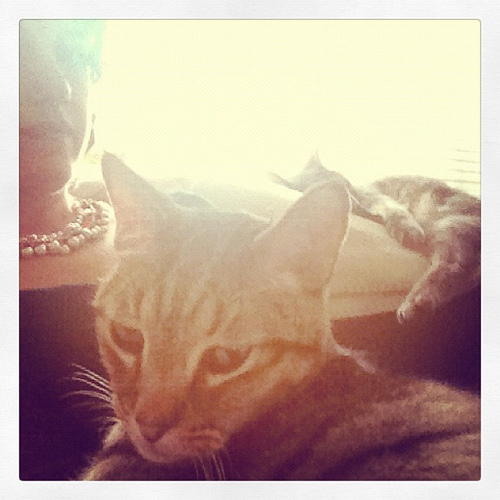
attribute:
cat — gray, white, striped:
[36, 160, 378, 453]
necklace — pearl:
[28, 193, 113, 258]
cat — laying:
[294, 152, 498, 332]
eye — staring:
[213, 339, 258, 385]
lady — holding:
[28, 35, 357, 448]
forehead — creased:
[102, 245, 334, 355]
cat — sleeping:
[292, 131, 493, 338]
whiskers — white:
[44, 352, 252, 472]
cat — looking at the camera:
[91, 300, 281, 423]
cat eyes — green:
[88, 274, 270, 395]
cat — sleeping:
[295, 150, 472, 270]